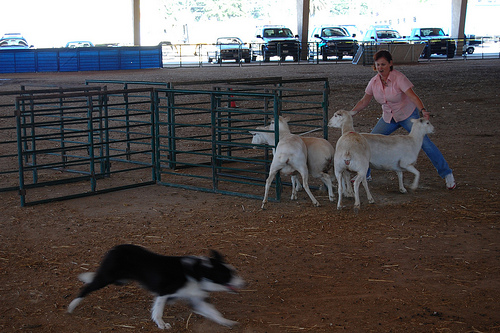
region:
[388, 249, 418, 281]
part of a surface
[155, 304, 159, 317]
leg of a dog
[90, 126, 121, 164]
part of a rail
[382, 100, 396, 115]
part of a shirt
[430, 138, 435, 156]
part of a jeans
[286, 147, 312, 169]
part of a sheep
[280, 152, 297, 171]
back of a sheep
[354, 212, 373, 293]
part of a surface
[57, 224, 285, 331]
herding dog running around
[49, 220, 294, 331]
australian sheep dog running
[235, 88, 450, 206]
shorn sheep being penned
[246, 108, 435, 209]
herd of shorn sheep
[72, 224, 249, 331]
black and white herding dog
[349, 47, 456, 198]
woman in a pink shirt and blue jeans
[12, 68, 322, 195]
metal pen for cattle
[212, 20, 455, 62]
line of parked cars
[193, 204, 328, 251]
dirt floor scattered with hay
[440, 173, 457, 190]
white tennis show flexed in dirt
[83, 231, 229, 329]
the dog is black and white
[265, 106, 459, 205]
the shhep are four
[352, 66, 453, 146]
her shirt is pink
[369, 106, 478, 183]
the jeans are blue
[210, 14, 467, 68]
the cars are parked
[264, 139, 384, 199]
the tails are short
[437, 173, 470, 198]
the shoes are white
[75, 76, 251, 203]
the frame is mettalic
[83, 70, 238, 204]
the frame is blue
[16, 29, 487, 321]
the scene is outdoors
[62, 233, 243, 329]
a black and white dog running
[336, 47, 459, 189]
a woman in a pink shirt and jeans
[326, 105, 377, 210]
a sheared sheep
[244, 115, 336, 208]
a pair of sheared sheep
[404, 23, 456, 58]
the front end of a pickup truck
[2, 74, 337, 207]
a pen with green fencing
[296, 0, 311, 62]
a support post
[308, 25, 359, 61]
the front end of an SUV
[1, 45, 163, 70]
a blue wall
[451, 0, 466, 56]
a cream colored support post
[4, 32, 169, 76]
Blue divider wall with cars behind it.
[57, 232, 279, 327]
Black and white dog running.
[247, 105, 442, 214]
Small shaven sheep with light beige fur.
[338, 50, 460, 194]
Sheepkeeper lady wearing a pink shirt and blue jeans.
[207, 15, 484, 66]
A row of cars in the background of a farmhouse.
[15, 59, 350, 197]
Iron square cage area with long skinny bars.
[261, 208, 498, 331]
Flat soiled ground with pieces of hay ontop.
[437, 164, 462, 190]
White sneaker being wore by a female sheepkeeper.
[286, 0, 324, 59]
Wooden pillar adjacent to a SUV.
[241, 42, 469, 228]
Female sheepkeeper trying to direct sheep inside of a caged area.